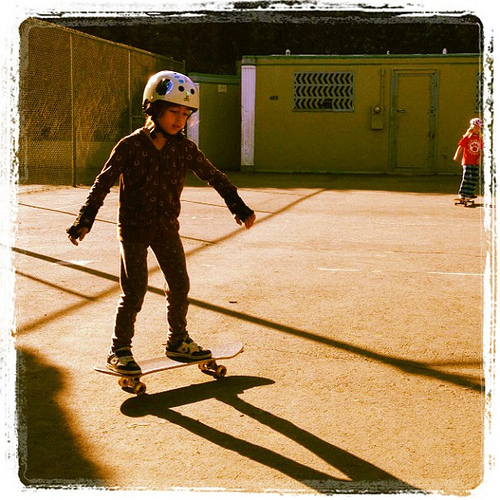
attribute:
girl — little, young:
[69, 69, 255, 376]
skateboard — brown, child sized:
[97, 342, 248, 396]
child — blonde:
[453, 117, 486, 207]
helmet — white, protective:
[143, 70, 198, 115]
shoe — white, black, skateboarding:
[165, 335, 214, 364]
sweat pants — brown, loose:
[113, 231, 191, 350]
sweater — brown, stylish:
[82, 129, 235, 241]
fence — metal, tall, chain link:
[18, 25, 188, 186]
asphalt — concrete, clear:
[19, 174, 482, 490]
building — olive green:
[186, 54, 485, 179]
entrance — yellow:
[393, 69, 436, 176]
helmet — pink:
[467, 118, 480, 130]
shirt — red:
[459, 133, 483, 161]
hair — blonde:
[468, 125, 484, 141]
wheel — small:
[216, 364, 228, 379]